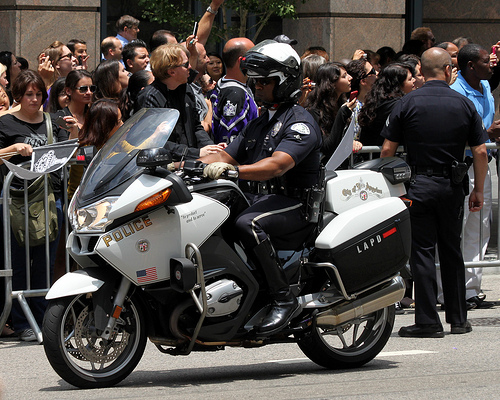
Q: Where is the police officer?
A: On a motorcycle.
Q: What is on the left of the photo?
A: Front tire of motorcycle.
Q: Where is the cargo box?
A: On the motorcycle.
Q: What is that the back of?
A: Standing police officer.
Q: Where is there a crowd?
A: Behind a fence.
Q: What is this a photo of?
A: Cop on a bike.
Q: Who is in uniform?
A: The police officers.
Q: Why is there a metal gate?
A: Keep people contained.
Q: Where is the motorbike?
A: On the street.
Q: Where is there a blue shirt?
A: Man on right.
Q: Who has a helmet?
A: Cop on bike.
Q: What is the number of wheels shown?
A: 2.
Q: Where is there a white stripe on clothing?
A: Bike cop pants.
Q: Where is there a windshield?
A: Front of bike.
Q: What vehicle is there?
A: Motorcycle.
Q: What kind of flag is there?
A: American.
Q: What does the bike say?
A: LAPD.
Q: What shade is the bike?
A: White.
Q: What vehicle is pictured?
A: Motorcycle.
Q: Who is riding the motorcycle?
A: Policeman.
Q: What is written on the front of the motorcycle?
A: POLICE.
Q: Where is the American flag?
A: On the motorcycle.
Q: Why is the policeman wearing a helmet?
A: Protection.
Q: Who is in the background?
A: A crowd of people.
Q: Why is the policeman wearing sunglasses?
A: Protect eyes from sun.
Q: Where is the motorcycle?
A: On the road.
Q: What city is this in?
A: LA.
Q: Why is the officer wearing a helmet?
A: He is on a motorcycle.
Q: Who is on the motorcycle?
A: The officer.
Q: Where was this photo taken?
A: LA.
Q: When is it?
A: Day time.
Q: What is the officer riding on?
A: A motorcycle.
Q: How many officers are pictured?
A: 2.